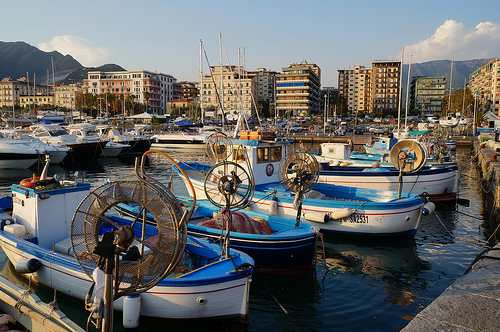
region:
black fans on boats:
[77, 137, 440, 297]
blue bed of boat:
[56, 190, 387, 272]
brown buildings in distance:
[14, 58, 492, 122]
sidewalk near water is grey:
[420, 265, 499, 325]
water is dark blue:
[325, 274, 390, 330]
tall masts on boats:
[185, 27, 280, 148]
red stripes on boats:
[295, 165, 464, 226]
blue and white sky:
[370, 12, 498, 58]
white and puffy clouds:
[372, 11, 499, 62]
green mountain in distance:
[1, 40, 126, 77]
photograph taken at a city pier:
[20, 45, 490, 320]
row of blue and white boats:
[2, 120, 459, 295]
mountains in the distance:
[1, 33, 123, 76]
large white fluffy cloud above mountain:
[387, 16, 499, 66]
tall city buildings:
[2, 45, 499, 112]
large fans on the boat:
[67, 168, 187, 320]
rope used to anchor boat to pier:
[230, 249, 306, 330]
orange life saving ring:
[16, 170, 57, 193]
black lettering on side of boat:
[315, 214, 387, 224]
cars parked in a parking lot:
[269, 110, 403, 131]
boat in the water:
[301, 144, 461, 205]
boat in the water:
[166, 149, 426, 244]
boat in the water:
[81, 178, 321, 281]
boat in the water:
[4, 176, 266, 316]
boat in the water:
[2, 123, 41, 171]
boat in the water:
[32, 120, 107, 164]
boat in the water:
[72, 120, 132, 164]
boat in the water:
[107, 125, 156, 165]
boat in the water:
[355, 133, 395, 162]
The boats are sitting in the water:
[20, 112, 497, 327]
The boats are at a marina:
[0, 150, 495, 328]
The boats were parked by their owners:
[5, 155, 496, 312]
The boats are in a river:
[11, 160, 489, 316]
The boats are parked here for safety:
[0, 152, 490, 323]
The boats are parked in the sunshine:
[0, 150, 482, 317]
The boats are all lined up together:
[10, 135, 496, 314]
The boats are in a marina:
[10, 135, 496, 322]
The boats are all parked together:
[17, 137, 482, 323]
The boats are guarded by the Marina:
[5, 147, 495, 325]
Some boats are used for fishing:
[3, 151, 493, 323]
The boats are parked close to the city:
[1, 86, 486, 322]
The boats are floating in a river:
[0, 166, 490, 316]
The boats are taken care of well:
[0, 141, 470, 321]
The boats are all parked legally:
[1, 160, 496, 320]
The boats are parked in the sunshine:
[15, 145, 490, 320]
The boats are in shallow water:
[0, 151, 470, 311]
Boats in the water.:
[53, 161, 442, 282]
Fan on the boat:
[203, 162, 252, 209]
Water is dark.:
[322, 240, 394, 321]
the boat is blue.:
[188, 205, 320, 256]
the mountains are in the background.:
[7, 35, 115, 80]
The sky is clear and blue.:
[87, 15, 439, 71]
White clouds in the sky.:
[397, 15, 494, 65]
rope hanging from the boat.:
[251, 278, 293, 322]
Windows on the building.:
[216, 84, 254, 111]